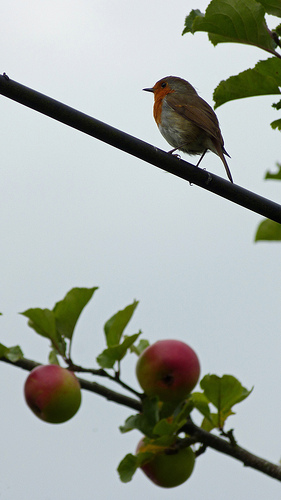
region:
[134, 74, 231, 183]
small bird on a branch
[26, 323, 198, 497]
this tree has applese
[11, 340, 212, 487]
there are three apples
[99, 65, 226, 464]
the bird is above the apples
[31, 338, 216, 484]
the apples are green and red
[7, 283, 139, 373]
the branch has green leaves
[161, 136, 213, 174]
the bird has two tiny legs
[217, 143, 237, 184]
the bird has tail feathers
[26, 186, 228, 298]
the sky is overcast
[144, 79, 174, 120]
the bird has an orange chest and face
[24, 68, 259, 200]
bird perched on straight rod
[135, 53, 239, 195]
grey bird with orange markings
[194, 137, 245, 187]
long tail feather touching rod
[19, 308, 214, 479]
apples growing on trees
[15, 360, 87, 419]
red and green hues of apple skin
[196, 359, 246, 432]
vein running down middle of leaf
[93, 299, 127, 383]
leaves growing on twigs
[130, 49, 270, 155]
leaf curving toward bird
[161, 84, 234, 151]
long and curved wing feathers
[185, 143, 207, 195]
claw curled around bottom of rod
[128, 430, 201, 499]
green and red fruit hanging from tree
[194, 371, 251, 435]
leaf is green and small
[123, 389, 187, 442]
leaf is green and small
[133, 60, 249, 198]
Bird has a orange face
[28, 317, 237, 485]
Fruit is growing on a tree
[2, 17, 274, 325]
The sky is powder blue in color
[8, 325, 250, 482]
Fruit is green and magenta colored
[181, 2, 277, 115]
Leaves on the trees are green in color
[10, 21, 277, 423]
Photo was taken in the daytime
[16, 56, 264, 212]
Bird is standing on a thick wire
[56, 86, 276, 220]
The wire the bird is on is black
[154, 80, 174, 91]
Birds eye is black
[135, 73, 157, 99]
Bird's beak is dark colored